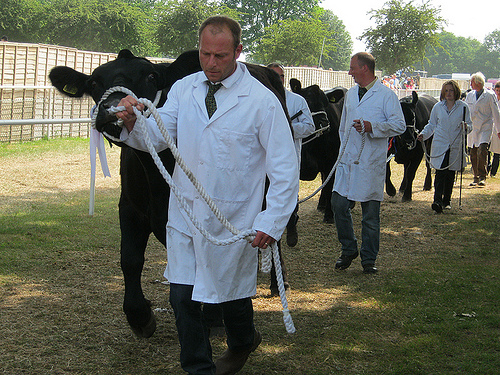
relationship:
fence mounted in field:
[6, 25, 88, 120] [0, 139, 120, 373]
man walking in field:
[114, 16, 299, 374] [94, 14, 299, 370]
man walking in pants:
[152, 251, 277, 374] [327, 189, 387, 279]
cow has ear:
[20, 38, 288, 360] [33, 56, 98, 106]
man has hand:
[114, 16, 299, 374] [107, 78, 153, 131]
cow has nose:
[20, 38, 288, 360] [95, 98, 134, 139]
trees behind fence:
[99, 0, 154, 58] [6, 25, 88, 120]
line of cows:
[58, 42, 452, 335] [20, 38, 288, 360]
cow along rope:
[20, 38, 288, 360] [129, 114, 235, 229]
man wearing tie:
[114, 16, 299, 374] [185, 75, 240, 133]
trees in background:
[65, 2, 178, 48] [31, 16, 329, 87]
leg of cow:
[89, 200, 183, 332] [20, 38, 288, 360]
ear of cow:
[33, 56, 98, 106] [20, 38, 288, 360]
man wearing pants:
[114, 16, 299, 374] [329, 191, 380, 267]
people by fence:
[58, 42, 452, 335] [6, 25, 88, 120]